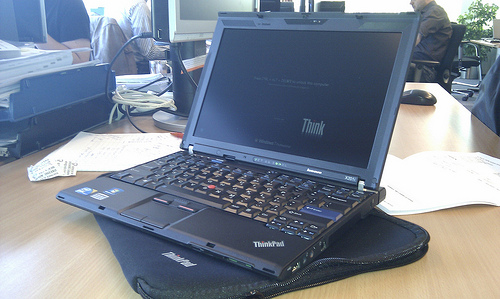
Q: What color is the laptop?
A: Black.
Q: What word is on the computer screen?
A: Think.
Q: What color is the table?
A: Tan.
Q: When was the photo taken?
A: Daytime.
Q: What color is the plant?
A: Green.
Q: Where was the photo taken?
A: Office.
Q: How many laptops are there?
A: One.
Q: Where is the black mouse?
A: Behind the laptop.